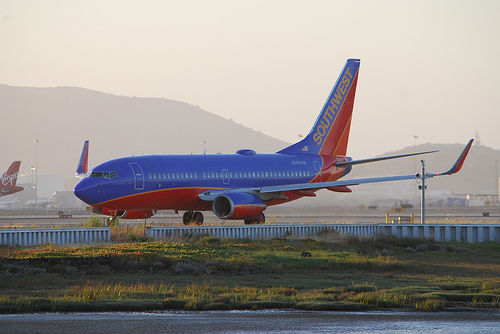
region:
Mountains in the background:
[0, 77, 499, 199]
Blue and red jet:
[76, 54, 478, 230]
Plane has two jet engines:
[103, 189, 270, 226]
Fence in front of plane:
[3, 220, 498, 250]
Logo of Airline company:
[306, 62, 356, 147]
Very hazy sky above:
[1, 2, 498, 159]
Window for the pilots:
[87, 168, 118, 179]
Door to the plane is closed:
[127, 161, 149, 190]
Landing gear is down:
[180, 204, 269, 227]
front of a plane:
[62, 132, 156, 222]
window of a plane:
[77, 159, 117, 181]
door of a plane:
[120, 159, 157, 194]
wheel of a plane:
[173, 201, 214, 231]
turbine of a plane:
[219, 191, 243, 221]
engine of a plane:
[207, 193, 242, 224]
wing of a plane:
[390, 149, 495, 191]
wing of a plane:
[279, 63, 376, 151]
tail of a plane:
[270, 122, 374, 197]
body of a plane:
[139, 145, 297, 229]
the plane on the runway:
[56, 43, 491, 224]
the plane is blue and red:
[76, 65, 496, 218]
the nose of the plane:
[61, 180, 93, 197]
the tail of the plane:
[258, 55, 365, 176]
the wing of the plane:
[196, 135, 473, 195]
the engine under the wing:
[206, 188, 268, 220]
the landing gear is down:
[103, 210, 268, 230]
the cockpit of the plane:
[87, 164, 133, 186]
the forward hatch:
[127, 158, 151, 195]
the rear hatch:
[309, 155, 334, 186]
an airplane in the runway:
[71, 51, 479, 226]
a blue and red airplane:
[66, 53, 482, 235]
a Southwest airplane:
[69, 50, 481, 240]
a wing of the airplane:
[259, 136, 478, 196]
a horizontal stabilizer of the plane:
[332, 145, 442, 168]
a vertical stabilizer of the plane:
[272, 55, 364, 156]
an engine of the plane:
[208, 187, 270, 220]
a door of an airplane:
[127, 157, 146, 190]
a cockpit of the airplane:
[78, 164, 120, 184]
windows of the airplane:
[145, 168, 200, 183]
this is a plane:
[132, 153, 248, 246]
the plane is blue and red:
[128, 113, 238, 280]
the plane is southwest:
[120, 157, 285, 329]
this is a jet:
[214, 212, 264, 230]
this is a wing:
[271, 161, 376, 248]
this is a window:
[130, 169, 261, 191]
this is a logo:
[299, 103, 403, 175]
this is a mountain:
[71, 106, 166, 145]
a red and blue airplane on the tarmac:
[20, 77, 445, 259]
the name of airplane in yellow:
[306, 30, 378, 184]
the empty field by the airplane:
[49, 253, 432, 303]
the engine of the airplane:
[189, 180, 277, 225]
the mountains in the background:
[33, 70, 236, 159]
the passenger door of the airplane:
[120, 156, 148, 204]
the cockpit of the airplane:
[77, 165, 131, 189]